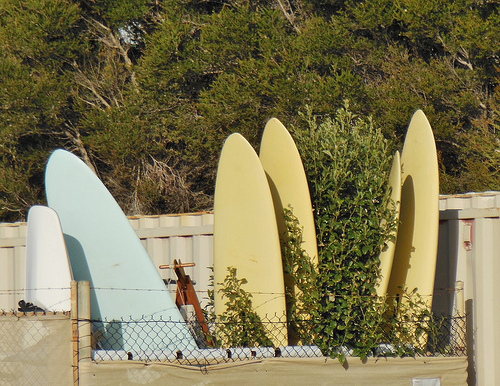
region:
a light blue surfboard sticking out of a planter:
[40, 157, 175, 367]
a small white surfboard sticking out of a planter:
[15, 205, 82, 300]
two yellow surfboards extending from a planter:
[235, 111, 307, 349]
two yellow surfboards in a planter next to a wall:
[378, 114, 443, 361]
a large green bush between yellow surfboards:
[309, 99, 391, 346]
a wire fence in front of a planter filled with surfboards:
[67, 315, 479, 359]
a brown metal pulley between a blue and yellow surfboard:
[160, 256, 229, 346]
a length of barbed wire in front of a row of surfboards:
[94, 281, 456, 306]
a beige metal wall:
[137, 212, 212, 252]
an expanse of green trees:
[41, 5, 496, 94]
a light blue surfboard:
[32, 142, 192, 359]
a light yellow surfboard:
[205, 120, 290, 350]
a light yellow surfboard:
[255, 110, 320, 345]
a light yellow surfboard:
[355, 145, 402, 332]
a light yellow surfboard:
[380, 100, 436, 345]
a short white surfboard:
[20, 200, 71, 315]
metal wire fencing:
[0, 272, 476, 380]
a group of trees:
[2, 0, 489, 222]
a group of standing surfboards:
[15, 105, 445, 355]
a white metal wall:
[1, 187, 498, 384]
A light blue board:
[42, 145, 194, 341]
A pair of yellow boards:
[204, 120, 328, 316]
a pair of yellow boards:
[380, 107, 460, 295]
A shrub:
[278, 87, 395, 335]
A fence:
[459, 190, 499, 279]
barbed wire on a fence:
[78, 282, 479, 309]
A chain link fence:
[98, 322, 446, 383]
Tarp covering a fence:
[3, 317, 65, 369]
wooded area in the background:
[39, 19, 286, 113]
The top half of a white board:
[22, 197, 126, 348]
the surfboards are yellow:
[185, 95, 483, 356]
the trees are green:
[4, 2, 458, 186]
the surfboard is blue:
[52, 152, 167, 383]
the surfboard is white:
[10, 194, 91, 338]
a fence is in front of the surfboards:
[0, 292, 480, 380]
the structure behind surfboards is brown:
[168, 187, 498, 351]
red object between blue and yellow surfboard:
[164, 244, 234, 355]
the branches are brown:
[68, 12, 218, 202]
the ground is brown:
[22, 331, 460, 382]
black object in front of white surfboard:
[5, 287, 55, 331]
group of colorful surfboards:
[8, 107, 459, 352]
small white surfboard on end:
[17, 198, 71, 317]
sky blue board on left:
[65, 130, 187, 362]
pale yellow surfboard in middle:
[207, 122, 272, 347]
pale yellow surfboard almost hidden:
[263, 108, 324, 352]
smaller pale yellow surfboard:
[383, 145, 401, 337]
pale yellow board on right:
[405, 96, 447, 343]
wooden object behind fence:
[157, 258, 215, 348]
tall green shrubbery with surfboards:
[308, 103, 380, 350]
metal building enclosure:
[127, 201, 209, 268]